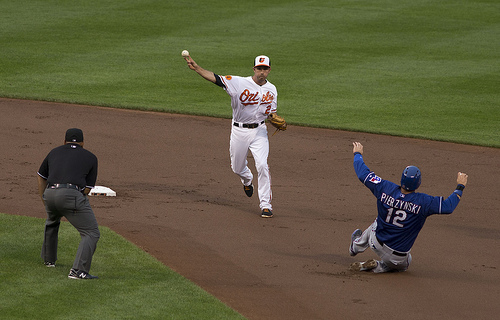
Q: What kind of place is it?
A: It is a field.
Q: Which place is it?
A: It is a field.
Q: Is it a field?
A: Yes, it is a field.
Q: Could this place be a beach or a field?
A: It is a field.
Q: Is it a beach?
A: No, it is a field.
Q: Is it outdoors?
A: Yes, it is outdoors.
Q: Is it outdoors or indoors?
A: It is outdoors.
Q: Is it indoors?
A: No, it is outdoors.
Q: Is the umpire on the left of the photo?
A: Yes, the umpire is on the left of the image.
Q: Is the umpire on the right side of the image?
A: No, the umpire is on the left of the image.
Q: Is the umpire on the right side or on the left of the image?
A: The umpire is on the left of the image.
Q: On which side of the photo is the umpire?
A: The umpire is on the left of the image.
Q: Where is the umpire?
A: The umpire is on the grass.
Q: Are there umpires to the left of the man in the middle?
A: Yes, there is an umpire to the left of the man.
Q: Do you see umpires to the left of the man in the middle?
A: Yes, there is an umpire to the left of the man.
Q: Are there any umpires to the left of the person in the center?
A: Yes, there is an umpire to the left of the man.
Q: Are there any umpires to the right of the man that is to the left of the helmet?
A: No, the umpire is to the left of the man.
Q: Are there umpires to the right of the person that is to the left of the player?
A: No, the umpire is to the left of the man.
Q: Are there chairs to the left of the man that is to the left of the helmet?
A: No, there is an umpire to the left of the man.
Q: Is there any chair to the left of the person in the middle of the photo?
A: No, there is an umpire to the left of the man.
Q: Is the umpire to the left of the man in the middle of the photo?
A: Yes, the umpire is to the left of the man.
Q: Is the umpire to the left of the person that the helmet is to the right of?
A: Yes, the umpire is to the left of the man.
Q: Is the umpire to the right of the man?
A: No, the umpire is to the left of the man.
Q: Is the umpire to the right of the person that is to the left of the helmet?
A: No, the umpire is to the left of the man.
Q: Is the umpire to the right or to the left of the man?
A: The umpire is to the left of the man.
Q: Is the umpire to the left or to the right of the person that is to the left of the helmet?
A: The umpire is to the left of the man.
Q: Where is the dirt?
A: The dirt is on the field.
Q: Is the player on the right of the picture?
A: Yes, the player is on the right of the image.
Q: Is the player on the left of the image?
A: No, the player is on the right of the image.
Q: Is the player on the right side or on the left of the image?
A: The player is on the right of the image.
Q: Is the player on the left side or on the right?
A: The player is on the right of the image.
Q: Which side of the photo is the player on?
A: The player is on the right of the image.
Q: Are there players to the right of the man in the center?
A: Yes, there is a player to the right of the man.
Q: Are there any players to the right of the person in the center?
A: Yes, there is a player to the right of the man.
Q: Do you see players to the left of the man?
A: No, the player is to the right of the man.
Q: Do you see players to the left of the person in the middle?
A: No, the player is to the right of the man.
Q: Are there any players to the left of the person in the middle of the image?
A: No, the player is to the right of the man.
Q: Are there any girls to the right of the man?
A: No, there is a player to the right of the man.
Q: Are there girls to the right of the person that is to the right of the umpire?
A: No, there is a player to the right of the man.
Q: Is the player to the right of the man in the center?
A: Yes, the player is to the right of the man.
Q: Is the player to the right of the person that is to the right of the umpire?
A: Yes, the player is to the right of the man.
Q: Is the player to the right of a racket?
A: No, the player is to the right of the man.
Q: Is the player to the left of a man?
A: No, the player is to the right of a man.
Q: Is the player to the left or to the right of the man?
A: The player is to the right of the man.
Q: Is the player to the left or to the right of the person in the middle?
A: The player is to the right of the man.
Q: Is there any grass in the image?
A: Yes, there is grass.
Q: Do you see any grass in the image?
A: Yes, there is grass.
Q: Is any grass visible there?
A: Yes, there is grass.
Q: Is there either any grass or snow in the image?
A: Yes, there is grass.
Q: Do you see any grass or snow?
A: Yes, there is grass.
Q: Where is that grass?
A: The grass is on the field.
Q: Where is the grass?
A: The grass is on the field.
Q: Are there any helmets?
A: Yes, there is a helmet.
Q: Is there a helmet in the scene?
A: Yes, there is a helmet.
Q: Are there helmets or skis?
A: Yes, there is a helmet.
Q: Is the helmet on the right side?
A: Yes, the helmet is on the right of the image.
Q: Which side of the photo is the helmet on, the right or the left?
A: The helmet is on the right of the image.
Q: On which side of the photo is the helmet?
A: The helmet is on the right of the image.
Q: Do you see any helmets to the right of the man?
A: Yes, there is a helmet to the right of the man.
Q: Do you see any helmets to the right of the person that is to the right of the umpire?
A: Yes, there is a helmet to the right of the man.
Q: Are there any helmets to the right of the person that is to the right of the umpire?
A: Yes, there is a helmet to the right of the man.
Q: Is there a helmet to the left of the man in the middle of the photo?
A: No, the helmet is to the right of the man.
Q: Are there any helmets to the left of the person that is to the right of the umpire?
A: No, the helmet is to the right of the man.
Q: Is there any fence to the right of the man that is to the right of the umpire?
A: No, there is a helmet to the right of the man.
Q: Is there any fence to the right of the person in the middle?
A: No, there is a helmet to the right of the man.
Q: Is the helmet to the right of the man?
A: Yes, the helmet is to the right of the man.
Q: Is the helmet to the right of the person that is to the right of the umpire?
A: Yes, the helmet is to the right of the man.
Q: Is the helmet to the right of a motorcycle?
A: No, the helmet is to the right of the man.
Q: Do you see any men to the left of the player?
A: Yes, there is a man to the left of the player.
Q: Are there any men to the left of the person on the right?
A: Yes, there is a man to the left of the player.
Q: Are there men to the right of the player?
A: No, the man is to the left of the player.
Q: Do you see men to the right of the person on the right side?
A: No, the man is to the left of the player.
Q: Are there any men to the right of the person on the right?
A: No, the man is to the left of the player.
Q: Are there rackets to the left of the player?
A: No, there is a man to the left of the player.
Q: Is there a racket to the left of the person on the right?
A: No, there is a man to the left of the player.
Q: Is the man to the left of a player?
A: Yes, the man is to the left of a player.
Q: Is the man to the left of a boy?
A: No, the man is to the left of a player.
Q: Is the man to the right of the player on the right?
A: No, the man is to the left of the player.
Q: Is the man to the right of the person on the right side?
A: No, the man is to the left of the player.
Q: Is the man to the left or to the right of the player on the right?
A: The man is to the left of the player.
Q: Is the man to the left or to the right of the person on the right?
A: The man is to the left of the player.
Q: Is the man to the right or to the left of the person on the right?
A: The man is to the left of the player.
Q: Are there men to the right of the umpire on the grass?
A: Yes, there is a man to the right of the umpire.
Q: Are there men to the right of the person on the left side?
A: Yes, there is a man to the right of the umpire.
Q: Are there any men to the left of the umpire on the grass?
A: No, the man is to the right of the umpire.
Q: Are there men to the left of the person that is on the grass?
A: No, the man is to the right of the umpire.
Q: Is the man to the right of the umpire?
A: Yes, the man is to the right of the umpire.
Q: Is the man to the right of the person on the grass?
A: Yes, the man is to the right of the umpire.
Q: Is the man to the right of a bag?
A: No, the man is to the right of the umpire.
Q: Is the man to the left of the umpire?
A: No, the man is to the right of the umpire.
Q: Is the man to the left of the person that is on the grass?
A: No, the man is to the right of the umpire.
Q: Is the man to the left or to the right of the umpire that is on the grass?
A: The man is to the right of the umpire.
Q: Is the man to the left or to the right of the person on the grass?
A: The man is to the right of the umpire.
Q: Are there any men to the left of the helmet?
A: Yes, there is a man to the left of the helmet.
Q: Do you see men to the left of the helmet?
A: Yes, there is a man to the left of the helmet.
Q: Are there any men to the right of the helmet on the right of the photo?
A: No, the man is to the left of the helmet.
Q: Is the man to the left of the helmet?
A: Yes, the man is to the left of the helmet.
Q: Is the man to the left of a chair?
A: No, the man is to the left of the helmet.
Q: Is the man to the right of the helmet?
A: No, the man is to the left of the helmet.